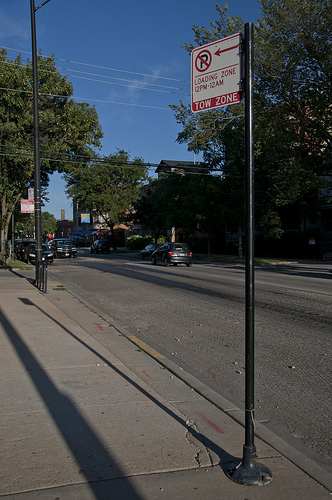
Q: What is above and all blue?
A: The sky.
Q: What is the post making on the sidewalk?
A: A shadow.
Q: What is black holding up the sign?
A: A post.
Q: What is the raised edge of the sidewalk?
A: Curb.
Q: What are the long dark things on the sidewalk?
A: Shadows.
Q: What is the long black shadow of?
A: A pole.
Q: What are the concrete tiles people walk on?
A: Sidewalk.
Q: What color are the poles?
A: Black.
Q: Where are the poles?
A: On the sidewalk.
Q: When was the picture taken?
A: Day time.